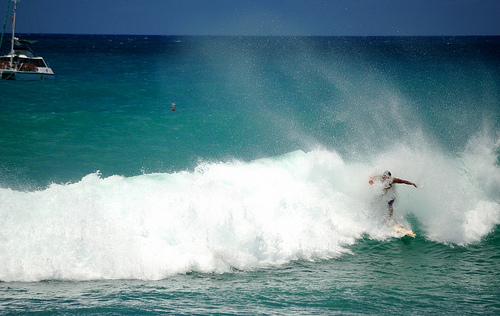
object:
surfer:
[367, 170, 419, 220]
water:
[280, 266, 376, 312]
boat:
[0, 48, 57, 82]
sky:
[0, 0, 499, 35]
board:
[390, 223, 417, 239]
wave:
[0, 156, 285, 281]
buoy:
[169, 101, 179, 112]